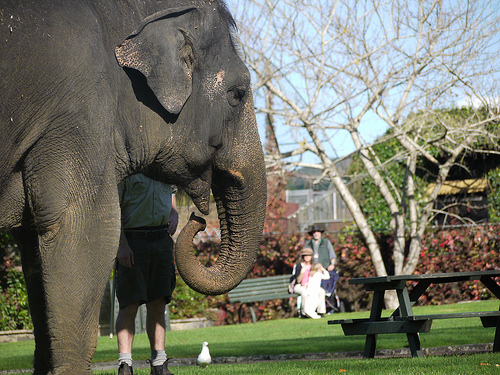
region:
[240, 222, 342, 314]
two people near looking at elephant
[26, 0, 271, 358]
large grey elephant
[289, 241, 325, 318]
woman siting on green bench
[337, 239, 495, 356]
green picnic table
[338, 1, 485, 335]
tree with no leaves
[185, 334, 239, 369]
white bird on ground near elephant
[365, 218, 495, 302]
bushes with red leaves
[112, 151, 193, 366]
man wearing shorts standing by elephant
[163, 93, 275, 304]
long trunk of elephant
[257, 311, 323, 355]
well manicured green lawn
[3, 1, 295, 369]
large elephant next to man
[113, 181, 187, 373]
man in shorts near elephant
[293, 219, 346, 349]
two people on bench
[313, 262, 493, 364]
picnic table in photograph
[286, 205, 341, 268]
two people wearing hats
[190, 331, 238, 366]
white bird on ground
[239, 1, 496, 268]
bare tree in photograph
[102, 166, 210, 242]
man in grey shirt in photo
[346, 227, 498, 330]
bush with red flowers in photo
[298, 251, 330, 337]
child with blonde hair on womans lap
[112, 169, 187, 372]
Person standing next to the elephant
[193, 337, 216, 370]
White bird standing on the ground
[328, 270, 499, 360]
Dark green picnic table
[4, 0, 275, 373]
Large gray elephant in the park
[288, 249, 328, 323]
Woman sitting on park bench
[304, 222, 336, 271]
Man standing behind the park bench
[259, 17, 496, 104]
Tree branches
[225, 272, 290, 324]
Park bench in the background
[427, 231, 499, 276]
Shrubbery behind the tree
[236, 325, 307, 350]
Green grass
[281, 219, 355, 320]
White man and woman with young girl.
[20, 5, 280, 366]
Docile Elephant at park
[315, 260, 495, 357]
Green wooden picnic table.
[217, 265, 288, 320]
Green wooden park bench.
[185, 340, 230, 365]
White bird sat on ground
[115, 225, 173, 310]
Green men's shorts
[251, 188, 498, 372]
Clear window overlooking park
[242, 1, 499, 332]
Tree with no leaves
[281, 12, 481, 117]
Blue sky with no clouds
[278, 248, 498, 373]
Bright green grass in park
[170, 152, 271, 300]
The elephant has a trunk.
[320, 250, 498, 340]
A picnic table.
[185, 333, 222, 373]
A little white bird.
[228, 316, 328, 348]
The grass is green.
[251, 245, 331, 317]
A person sitting on a bench.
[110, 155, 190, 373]
A person standing behind an elephant.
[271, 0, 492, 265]
A tree with no leaves on it.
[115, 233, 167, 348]
The person is wearing shorts.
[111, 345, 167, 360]
The person is wearing socks.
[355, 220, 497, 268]
A bush next to the tree.